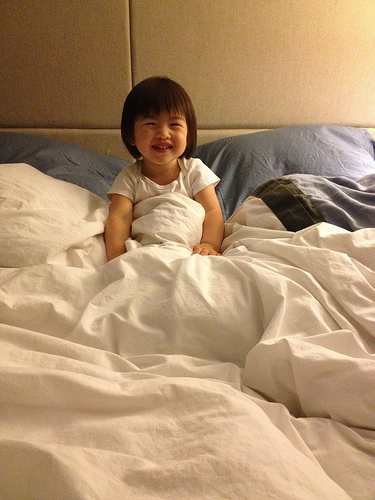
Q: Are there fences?
A: No, there are no fences.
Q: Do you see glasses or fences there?
A: No, there are no fences or glasses.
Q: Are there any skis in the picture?
A: No, there are no skis.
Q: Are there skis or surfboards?
A: No, there are no skis or surfboards.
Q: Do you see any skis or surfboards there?
A: No, there are no skis or surfboards.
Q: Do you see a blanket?
A: Yes, there is a blanket.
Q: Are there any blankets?
A: Yes, there is a blanket.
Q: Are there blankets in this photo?
A: Yes, there is a blanket.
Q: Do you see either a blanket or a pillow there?
A: Yes, there is a blanket.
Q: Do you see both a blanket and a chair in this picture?
A: No, there is a blanket but no chairs.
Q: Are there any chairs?
A: No, there are no chairs.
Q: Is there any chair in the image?
A: No, there are no chairs.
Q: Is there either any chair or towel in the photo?
A: No, there are no chairs or towels.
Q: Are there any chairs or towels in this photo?
A: No, there are no chairs or towels.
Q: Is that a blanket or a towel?
A: That is a blanket.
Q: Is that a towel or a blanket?
A: That is a blanket.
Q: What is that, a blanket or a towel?
A: That is a blanket.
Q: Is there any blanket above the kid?
A: Yes, there is a blanket above the kid.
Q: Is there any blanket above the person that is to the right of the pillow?
A: Yes, there is a blanket above the kid.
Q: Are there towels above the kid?
A: No, there is a blanket above the kid.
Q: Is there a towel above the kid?
A: No, there is a blanket above the kid.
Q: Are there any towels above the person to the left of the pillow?
A: No, there is a blanket above the kid.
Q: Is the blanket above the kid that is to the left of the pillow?
A: Yes, the blanket is above the child.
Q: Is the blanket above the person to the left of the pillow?
A: Yes, the blanket is above the child.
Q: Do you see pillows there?
A: Yes, there is a pillow.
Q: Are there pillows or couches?
A: Yes, there is a pillow.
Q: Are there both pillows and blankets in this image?
A: Yes, there are both a pillow and a blanket.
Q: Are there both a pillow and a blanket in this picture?
A: Yes, there are both a pillow and a blanket.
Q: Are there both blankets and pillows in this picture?
A: Yes, there are both a pillow and a blanket.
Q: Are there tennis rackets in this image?
A: No, there are no tennis rackets.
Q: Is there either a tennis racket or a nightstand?
A: No, there are no rackets or nightstands.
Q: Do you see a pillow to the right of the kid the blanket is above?
A: Yes, there is a pillow to the right of the child.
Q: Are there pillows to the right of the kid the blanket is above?
A: Yes, there is a pillow to the right of the child.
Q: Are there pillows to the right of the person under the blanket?
A: Yes, there is a pillow to the right of the child.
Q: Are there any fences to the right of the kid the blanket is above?
A: No, there is a pillow to the right of the kid.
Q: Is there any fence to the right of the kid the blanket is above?
A: No, there is a pillow to the right of the kid.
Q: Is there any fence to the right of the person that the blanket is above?
A: No, there is a pillow to the right of the kid.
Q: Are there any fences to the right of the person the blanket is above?
A: No, there is a pillow to the right of the kid.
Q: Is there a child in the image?
A: Yes, there is a child.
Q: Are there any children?
A: Yes, there is a child.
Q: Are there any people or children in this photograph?
A: Yes, there is a child.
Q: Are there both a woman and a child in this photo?
A: No, there is a child but no women.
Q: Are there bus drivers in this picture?
A: No, there are no bus drivers.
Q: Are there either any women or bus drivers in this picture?
A: No, there are no bus drivers or women.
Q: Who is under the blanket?
A: The kid is under the blanket.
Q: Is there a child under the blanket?
A: Yes, there is a child under the blanket.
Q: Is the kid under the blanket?
A: Yes, the kid is under the blanket.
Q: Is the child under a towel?
A: No, the child is under the blanket.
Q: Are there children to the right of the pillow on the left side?
A: Yes, there is a child to the right of the pillow.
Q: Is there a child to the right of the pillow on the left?
A: Yes, there is a child to the right of the pillow.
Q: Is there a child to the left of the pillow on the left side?
A: No, the child is to the right of the pillow.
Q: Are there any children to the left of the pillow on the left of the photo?
A: No, the child is to the right of the pillow.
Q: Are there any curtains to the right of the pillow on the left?
A: No, there is a child to the right of the pillow.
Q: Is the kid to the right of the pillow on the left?
A: Yes, the kid is to the right of the pillow.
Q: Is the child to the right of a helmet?
A: No, the child is to the right of the pillow.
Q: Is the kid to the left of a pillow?
A: No, the kid is to the right of a pillow.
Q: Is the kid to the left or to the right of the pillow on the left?
A: The kid is to the right of the pillow.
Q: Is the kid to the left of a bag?
A: No, the kid is to the left of the pillow.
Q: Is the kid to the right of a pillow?
A: No, the kid is to the left of a pillow.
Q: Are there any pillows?
A: Yes, there is a pillow.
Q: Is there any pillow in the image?
A: Yes, there is a pillow.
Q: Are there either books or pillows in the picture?
A: Yes, there is a pillow.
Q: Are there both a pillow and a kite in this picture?
A: No, there is a pillow but no kites.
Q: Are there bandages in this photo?
A: No, there are no bandages.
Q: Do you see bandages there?
A: No, there are no bandages.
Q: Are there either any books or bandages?
A: No, there are no bandages or books.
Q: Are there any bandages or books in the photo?
A: No, there are no bandages or books.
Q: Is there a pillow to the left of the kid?
A: Yes, there is a pillow to the left of the kid.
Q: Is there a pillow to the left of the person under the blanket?
A: Yes, there is a pillow to the left of the kid.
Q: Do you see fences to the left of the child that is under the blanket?
A: No, there is a pillow to the left of the kid.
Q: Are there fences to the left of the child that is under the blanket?
A: No, there is a pillow to the left of the kid.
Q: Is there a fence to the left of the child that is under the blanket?
A: No, there is a pillow to the left of the kid.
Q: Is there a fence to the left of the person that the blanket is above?
A: No, there is a pillow to the left of the kid.